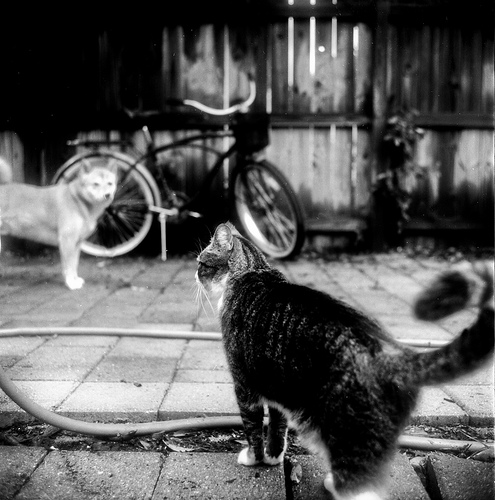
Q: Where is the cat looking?
A: Away from the camera.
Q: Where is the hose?
A: On the patio.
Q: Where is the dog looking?
A: Towards the cat.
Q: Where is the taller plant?
A: Against the fence.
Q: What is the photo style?
A: Black and white.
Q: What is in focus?
A: The cat.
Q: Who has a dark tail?
A: The cat.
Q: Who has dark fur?
A: The cat.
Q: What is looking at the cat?
A: Dog.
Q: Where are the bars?
A: Storefront.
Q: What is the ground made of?
A: Bricks.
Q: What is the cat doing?
A: Standing.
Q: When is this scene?
A: Early evening.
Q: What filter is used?
A: Black and white.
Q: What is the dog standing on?
A: Sidewalk.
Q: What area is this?
A: City.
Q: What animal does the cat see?
A: A dog.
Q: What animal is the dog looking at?
A: A cat.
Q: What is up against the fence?
A: A bike.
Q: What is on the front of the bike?
A: A basket.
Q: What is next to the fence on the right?
A: A small plant.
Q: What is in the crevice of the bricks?
A: Leaves.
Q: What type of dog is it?
A: A husky.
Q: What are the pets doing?
A: Patrolling the neighborhood.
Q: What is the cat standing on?
A: A patio.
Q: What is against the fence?
A: A bicycle.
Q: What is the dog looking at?
A: The cat.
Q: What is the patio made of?
A: Cement blocks.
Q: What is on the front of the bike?
A: A basket.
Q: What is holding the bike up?
A: A kickstand.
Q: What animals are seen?
A: Cat and dog.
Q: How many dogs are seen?
A: 1.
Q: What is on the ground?
A: Tiles.